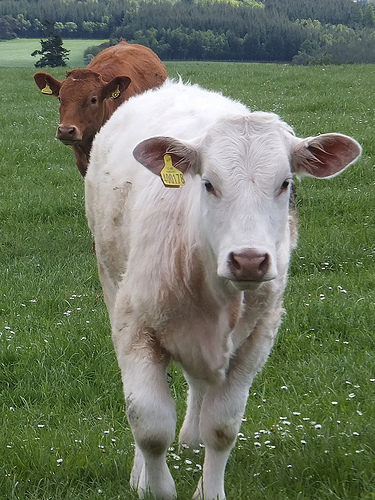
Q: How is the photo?
A: Clear.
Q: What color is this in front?
A: White.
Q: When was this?
A: Daytime.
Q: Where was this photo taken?
A: In a pasture.